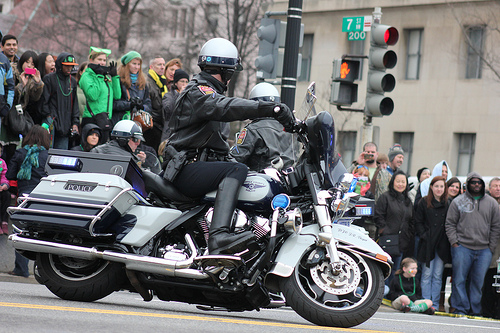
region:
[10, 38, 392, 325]
Police on a motorcycle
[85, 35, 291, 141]
Helmets on police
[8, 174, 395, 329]
Wheels of the motorcycle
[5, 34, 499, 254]
A crowd of people on the sidewalk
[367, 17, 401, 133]
A traffic sign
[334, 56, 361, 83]
The bright red hand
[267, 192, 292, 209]
A blue round light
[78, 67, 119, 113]
The bright green jacket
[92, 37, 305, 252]
Three cops in the picture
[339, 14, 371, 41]
Green sign with numbers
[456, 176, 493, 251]
the man has a grey hoodie on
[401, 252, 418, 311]
the boy is sitting on the ground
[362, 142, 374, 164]
the man is taking a photo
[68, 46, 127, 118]
the girl is wearing a green jacket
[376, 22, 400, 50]
the light is red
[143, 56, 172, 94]
the man has on yellow scarf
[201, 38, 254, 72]
the policemans helmet is white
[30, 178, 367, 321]
the policeman is riding a motorcycle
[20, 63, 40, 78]
the girl has a pink phone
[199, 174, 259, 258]
the policeman has black boots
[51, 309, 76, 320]
part of a road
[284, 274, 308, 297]
part of a wheel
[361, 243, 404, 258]
part of a guard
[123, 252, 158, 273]
part of a metal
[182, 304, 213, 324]
part of a yellow line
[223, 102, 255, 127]
part of a coat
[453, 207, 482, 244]
part of a sweater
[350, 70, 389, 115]
part of a traffic light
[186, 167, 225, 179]
part of a trouser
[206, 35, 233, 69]
part of a helmet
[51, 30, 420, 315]
two motorcyclists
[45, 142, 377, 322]
a silver and black motorcycle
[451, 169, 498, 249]
a man wearing a gray hoodie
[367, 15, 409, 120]
a street light set on red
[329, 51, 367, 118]
a pedestrian light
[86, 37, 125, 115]
a woman wearing green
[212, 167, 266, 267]
dark leather boots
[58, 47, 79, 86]
man wearing a green and orange cap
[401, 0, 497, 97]
two windows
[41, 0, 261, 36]
trees without foliage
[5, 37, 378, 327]
Man riding motor bike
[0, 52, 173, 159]
People watching bike riders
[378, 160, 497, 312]
People dressed in warm clothes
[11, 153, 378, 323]
Black and grey motor bike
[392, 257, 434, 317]
Girl sitting on ground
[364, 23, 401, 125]
Traffic lights on pole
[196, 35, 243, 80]
Black and white helmet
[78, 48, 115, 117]
Lady wearing green jacket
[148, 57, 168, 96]
Man wearing yellow scarf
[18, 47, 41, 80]
Lady holding pink cellphone